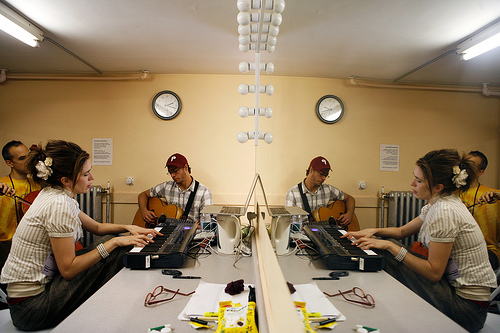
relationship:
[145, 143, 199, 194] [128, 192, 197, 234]
man with guitar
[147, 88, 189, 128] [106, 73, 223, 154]
clock on wall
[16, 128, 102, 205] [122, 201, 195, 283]
lady playing keyboard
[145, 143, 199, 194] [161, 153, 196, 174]
man wearing cap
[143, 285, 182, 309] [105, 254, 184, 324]
eyeglasses on counter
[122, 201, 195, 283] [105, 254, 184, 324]
keyboard on counter